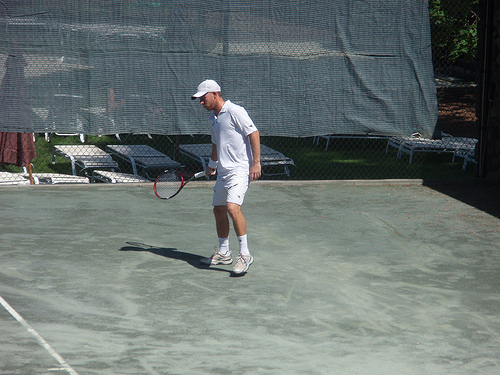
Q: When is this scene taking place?
A: Daytime.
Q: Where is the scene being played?
A: Tennis court.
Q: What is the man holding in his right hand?
A: Tennis racket.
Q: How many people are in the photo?
A: One.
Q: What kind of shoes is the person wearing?
A: Sneakers.